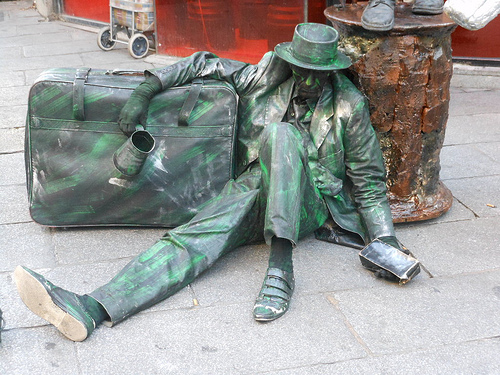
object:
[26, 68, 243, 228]
suitcase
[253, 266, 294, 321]
shoe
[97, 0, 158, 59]
cart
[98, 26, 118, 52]
wheel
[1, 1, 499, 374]
sidewalk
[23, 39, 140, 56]
square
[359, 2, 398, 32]
shoe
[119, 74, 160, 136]
glove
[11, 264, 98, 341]
shoe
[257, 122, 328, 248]
pant leg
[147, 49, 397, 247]
jacket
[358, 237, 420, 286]
item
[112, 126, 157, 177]
can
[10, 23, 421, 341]
beggar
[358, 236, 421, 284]
box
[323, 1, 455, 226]
pedestal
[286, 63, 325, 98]
face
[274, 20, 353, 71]
fedora hat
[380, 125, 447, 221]
lower portion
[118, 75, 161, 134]
hand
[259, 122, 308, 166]
knee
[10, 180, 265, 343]
leg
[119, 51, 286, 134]
arm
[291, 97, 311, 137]
tie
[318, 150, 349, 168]
pocket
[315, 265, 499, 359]
tile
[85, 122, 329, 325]
pants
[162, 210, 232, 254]
wrinkles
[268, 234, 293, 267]
sock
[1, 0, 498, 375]
ground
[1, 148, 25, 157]
crack